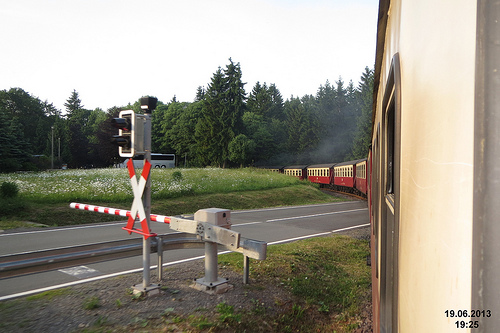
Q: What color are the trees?
A: The trees are green.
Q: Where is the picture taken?
A: Outside near a train track.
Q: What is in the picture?
A: A big train and tree and grass and a street.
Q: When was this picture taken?
A: It was taken in the day time.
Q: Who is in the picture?
A: Nobody is in the picture.